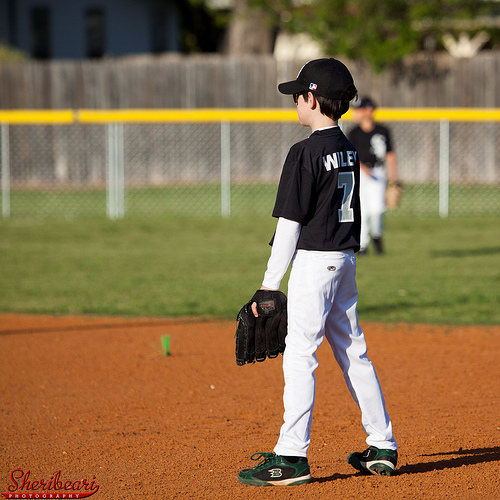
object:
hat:
[278, 57, 356, 101]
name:
[322, 149, 357, 170]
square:
[12, 131, 36, 162]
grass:
[78, 244, 180, 289]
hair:
[324, 101, 349, 121]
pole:
[218, 122, 232, 217]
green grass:
[409, 186, 499, 283]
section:
[95, 402, 212, 497]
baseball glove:
[234, 287, 288, 366]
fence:
[0, 102, 499, 219]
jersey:
[271, 125, 366, 252]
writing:
[323, 147, 359, 224]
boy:
[233, 44, 418, 486]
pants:
[274, 240, 397, 462]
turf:
[0, 171, 499, 311]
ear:
[306, 92, 317, 112]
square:
[451, 122, 498, 217]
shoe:
[345, 442, 395, 474]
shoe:
[237, 453, 312, 487]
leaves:
[215, 0, 499, 76]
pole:
[0, 124, 15, 215]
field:
[3, 179, 498, 500]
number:
[335, 165, 365, 225]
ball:
[161, 334, 171, 358]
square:
[185, 130, 195, 140]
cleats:
[236, 451, 314, 487]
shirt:
[271, 126, 363, 253]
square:
[54, 146, 68, 159]